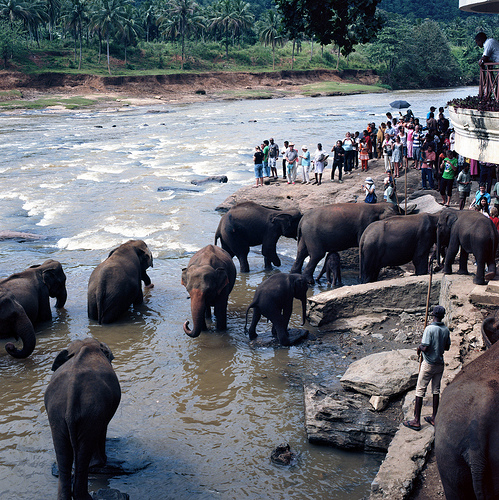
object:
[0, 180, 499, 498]
foreground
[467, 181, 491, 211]
man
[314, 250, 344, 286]
elephant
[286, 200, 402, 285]
elephant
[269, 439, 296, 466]
boulders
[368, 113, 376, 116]
rock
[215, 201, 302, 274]
elephant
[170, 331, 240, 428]
reflection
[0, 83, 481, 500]
water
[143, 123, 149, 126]
rock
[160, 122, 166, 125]
rock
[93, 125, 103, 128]
rock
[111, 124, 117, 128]
rock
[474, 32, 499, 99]
man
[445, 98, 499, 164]
balcony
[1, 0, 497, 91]
jungle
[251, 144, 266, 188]
people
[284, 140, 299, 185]
man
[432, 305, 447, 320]
hair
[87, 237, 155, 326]
elephant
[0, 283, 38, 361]
elephant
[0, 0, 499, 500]
daytime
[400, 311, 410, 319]
rock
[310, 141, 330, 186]
person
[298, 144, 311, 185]
person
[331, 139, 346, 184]
person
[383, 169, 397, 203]
person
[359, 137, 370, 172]
person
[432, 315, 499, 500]
elephant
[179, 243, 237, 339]
elephant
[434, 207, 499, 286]
elephant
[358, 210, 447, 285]
elephant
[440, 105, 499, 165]
wall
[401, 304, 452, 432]
man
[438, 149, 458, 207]
man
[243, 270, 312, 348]
elephant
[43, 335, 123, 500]
elephant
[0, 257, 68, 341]
elephant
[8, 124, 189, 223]
river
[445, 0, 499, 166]
building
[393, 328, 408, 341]
rock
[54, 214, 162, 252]
rapids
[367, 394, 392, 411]
ledge rocks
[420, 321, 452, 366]
shirt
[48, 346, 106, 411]
back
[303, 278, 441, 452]
ledge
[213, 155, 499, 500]
bank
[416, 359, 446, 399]
pants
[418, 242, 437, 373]
pole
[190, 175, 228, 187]
rock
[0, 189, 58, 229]
rapids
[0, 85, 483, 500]
river